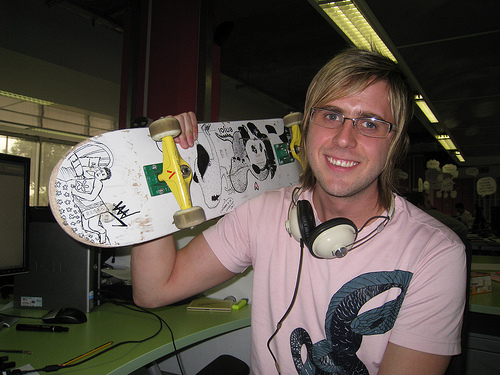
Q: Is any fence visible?
A: No, there are no fences.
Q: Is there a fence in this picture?
A: No, there are no fences.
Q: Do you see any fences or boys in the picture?
A: No, there are no fences or boys.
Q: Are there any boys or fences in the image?
A: No, there are no fences or boys.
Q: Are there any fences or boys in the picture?
A: No, there are no fences or boys.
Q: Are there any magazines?
A: No, there are no magazines.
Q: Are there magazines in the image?
A: No, there are no magazines.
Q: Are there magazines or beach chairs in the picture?
A: No, there are no magazines or beach chairs.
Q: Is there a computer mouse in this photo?
A: Yes, there is a computer mouse.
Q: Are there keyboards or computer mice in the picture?
A: Yes, there is a computer mouse.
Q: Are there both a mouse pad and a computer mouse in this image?
A: No, there is a computer mouse but no mouse pads.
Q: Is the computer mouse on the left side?
A: Yes, the computer mouse is on the left of the image.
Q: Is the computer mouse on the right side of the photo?
A: No, the computer mouse is on the left of the image.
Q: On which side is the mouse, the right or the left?
A: The mouse is on the left of the image.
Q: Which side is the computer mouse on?
A: The computer mouse is on the left of the image.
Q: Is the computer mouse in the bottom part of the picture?
A: Yes, the computer mouse is in the bottom of the image.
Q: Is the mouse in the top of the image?
A: No, the mouse is in the bottom of the image.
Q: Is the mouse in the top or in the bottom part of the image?
A: The mouse is in the bottom of the image.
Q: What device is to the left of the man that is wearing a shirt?
A: The device is a computer mouse.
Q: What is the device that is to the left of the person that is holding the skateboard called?
A: The device is a computer mouse.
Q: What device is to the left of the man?
A: The device is a computer mouse.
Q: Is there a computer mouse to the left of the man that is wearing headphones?
A: Yes, there is a computer mouse to the left of the man.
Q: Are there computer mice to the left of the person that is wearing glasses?
A: Yes, there is a computer mouse to the left of the man.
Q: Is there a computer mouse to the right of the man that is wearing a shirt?
A: No, the computer mouse is to the left of the man.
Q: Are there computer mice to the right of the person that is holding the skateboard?
A: No, the computer mouse is to the left of the man.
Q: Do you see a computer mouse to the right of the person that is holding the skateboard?
A: No, the computer mouse is to the left of the man.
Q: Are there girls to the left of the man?
A: No, there is a computer mouse to the left of the man.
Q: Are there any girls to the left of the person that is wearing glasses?
A: No, there is a computer mouse to the left of the man.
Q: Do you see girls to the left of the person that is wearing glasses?
A: No, there is a computer mouse to the left of the man.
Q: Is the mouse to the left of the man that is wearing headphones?
A: Yes, the mouse is to the left of the man.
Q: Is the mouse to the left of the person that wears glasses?
A: Yes, the mouse is to the left of the man.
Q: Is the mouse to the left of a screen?
A: No, the mouse is to the left of the man.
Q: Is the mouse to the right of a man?
A: No, the mouse is to the left of a man.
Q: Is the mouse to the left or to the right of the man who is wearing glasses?
A: The mouse is to the left of the man.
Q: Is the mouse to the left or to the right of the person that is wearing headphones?
A: The mouse is to the left of the man.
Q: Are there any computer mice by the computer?
A: Yes, there is a computer mouse by the computer.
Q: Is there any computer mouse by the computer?
A: Yes, there is a computer mouse by the computer.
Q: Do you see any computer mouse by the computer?
A: Yes, there is a computer mouse by the computer.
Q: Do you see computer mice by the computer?
A: Yes, there is a computer mouse by the computer.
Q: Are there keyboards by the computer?
A: No, there is a computer mouse by the computer.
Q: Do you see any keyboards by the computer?
A: No, there is a computer mouse by the computer.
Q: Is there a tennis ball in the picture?
A: No, there are no tennis balls.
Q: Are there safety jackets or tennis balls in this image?
A: No, there are no tennis balls or safety jackets.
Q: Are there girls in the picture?
A: No, there are no girls.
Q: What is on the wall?
A: The drawings are on the wall.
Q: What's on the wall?
A: The drawings are on the wall.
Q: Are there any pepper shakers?
A: No, there are no pepper shakers.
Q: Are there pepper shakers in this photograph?
A: No, there are no pepper shakers.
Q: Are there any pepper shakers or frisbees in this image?
A: No, there are no pepper shakers or frisbees.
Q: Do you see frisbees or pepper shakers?
A: No, there are no pepper shakers or frisbees.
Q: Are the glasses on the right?
A: Yes, the glasses are on the right of the image.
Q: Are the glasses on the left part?
A: No, the glasses are on the right of the image.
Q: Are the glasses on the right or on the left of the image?
A: The glasses are on the right of the image.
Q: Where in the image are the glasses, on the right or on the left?
A: The glasses are on the right of the image.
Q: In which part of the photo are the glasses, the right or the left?
A: The glasses are on the right of the image.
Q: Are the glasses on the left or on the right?
A: The glasses are on the right of the image.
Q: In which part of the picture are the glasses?
A: The glasses are on the right of the image.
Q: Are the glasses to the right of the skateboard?
A: Yes, the glasses are to the right of the skateboard.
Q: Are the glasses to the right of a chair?
A: No, the glasses are to the right of the skateboard.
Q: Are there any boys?
A: No, there are no boys.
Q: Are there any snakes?
A: Yes, there is a snake.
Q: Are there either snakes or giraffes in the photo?
A: Yes, there is a snake.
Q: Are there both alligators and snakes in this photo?
A: No, there is a snake but no alligators.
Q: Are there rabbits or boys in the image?
A: No, there are no boys or rabbits.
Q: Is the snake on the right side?
A: Yes, the snake is on the right of the image.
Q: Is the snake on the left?
A: No, the snake is on the right of the image.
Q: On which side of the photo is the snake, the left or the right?
A: The snake is on the right of the image.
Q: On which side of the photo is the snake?
A: The snake is on the right of the image.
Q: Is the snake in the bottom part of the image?
A: Yes, the snake is in the bottom of the image.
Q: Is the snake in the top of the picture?
A: No, the snake is in the bottom of the image.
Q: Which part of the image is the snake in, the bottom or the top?
A: The snake is in the bottom of the image.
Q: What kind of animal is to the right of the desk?
A: The animal is a snake.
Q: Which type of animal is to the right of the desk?
A: The animal is a snake.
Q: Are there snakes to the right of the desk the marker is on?
A: Yes, there is a snake to the right of the desk.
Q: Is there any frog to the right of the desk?
A: No, there is a snake to the right of the desk.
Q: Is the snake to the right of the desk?
A: Yes, the snake is to the right of the desk.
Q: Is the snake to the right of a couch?
A: No, the snake is to the right of the desk.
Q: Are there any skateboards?
A: Yes, there is a skateboard.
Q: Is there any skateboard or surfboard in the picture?
A: Yes, there is a skateboard.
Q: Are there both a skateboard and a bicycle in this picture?
A: No, there is a skateboard but no bicycles.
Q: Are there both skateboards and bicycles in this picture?
A: No, there is a skateboard but no bicycles.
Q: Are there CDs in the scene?
A: No, there are no cds.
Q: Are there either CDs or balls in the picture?
A: No, there are no CDs or balls.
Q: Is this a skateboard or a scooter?
A: This is a skateboard.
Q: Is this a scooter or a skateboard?
A: This is a skateboard.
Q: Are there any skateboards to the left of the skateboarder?
A: Yes, there is a skateboard to the left of the skateboarder.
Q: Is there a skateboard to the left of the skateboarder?
A: Yes, there is a skateboard to the left of the skateboarder.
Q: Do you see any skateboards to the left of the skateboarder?
A: Yes, there is a skateboard to the left of the skateboarder.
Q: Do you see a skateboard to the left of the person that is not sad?
A: Yes, there is a skateboard to the left of the skateboarder.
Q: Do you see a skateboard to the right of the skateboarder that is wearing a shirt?
A: No, the skateboard is to the left of the skateboarder.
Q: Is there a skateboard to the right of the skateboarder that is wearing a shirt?
A: No, the skateboard is to the left of the skateboarder.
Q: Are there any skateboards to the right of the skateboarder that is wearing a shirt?
A: No, the skateboard is to the left of the skateboarder.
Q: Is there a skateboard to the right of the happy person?
A: No, the skateboard is to the left of the skateboarder.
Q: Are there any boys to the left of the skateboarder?
A: No, there is a skateboard to the left of the skateboarder.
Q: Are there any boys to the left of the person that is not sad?
A: No, there is a skateboard to the left of the skateboarder.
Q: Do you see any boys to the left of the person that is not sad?
A: No, there is a skateboard to the left of the skateboarder.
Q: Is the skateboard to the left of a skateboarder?
A: Yes, the skateboard is to the left of a skateboarder.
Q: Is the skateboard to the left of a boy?
A: No, the skateboard is to the left of a skateboarder.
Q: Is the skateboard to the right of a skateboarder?
A: No, the skateboard is to the left of a skateboarder.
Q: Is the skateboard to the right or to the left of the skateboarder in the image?
A: The skateboard is to the left of the skateboarder.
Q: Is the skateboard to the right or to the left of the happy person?
A: The skateboard is to the left of the skateboarder.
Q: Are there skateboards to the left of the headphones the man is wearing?
A: Yes, there is a skateboard to the left of the headphones.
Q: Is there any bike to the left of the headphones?
A: No, there is a skateboard to the left of the headphones.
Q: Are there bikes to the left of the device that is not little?
A: No, there is a skateboard to the left of the headphones.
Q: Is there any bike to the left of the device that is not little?
A: No, there is a skateboard to the left of the headphones.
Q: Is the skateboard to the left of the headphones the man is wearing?
A: Yes, the skateboard is to the left of the headphones.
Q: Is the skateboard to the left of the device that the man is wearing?
A: Yes, the skateboard is to the left of the headphones.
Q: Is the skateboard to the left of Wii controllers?
A: No, the skateboard is to the left of the headphones.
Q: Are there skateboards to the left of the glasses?
A: Yes, there is a skateboard to the left of the glasses.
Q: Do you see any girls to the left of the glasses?
A: No, there is a skateboard to the left of the glasses.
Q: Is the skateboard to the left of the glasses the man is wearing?
A: Yes, the skateboard is to the left of the glasses.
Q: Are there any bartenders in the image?
A: No, there are no bartenders.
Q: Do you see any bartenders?
A: No, there are no bartenders.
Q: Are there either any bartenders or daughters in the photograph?
A: No, there are no bartenders or daughters.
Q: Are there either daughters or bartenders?
A: No, there are no bartenders or daughters.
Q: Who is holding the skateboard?
A: The man is holding the skateboard.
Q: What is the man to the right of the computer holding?
A: The man is holding the skateboard.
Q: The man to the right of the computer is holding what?
A: The man is holding the skateboard.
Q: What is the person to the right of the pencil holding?
A: The man is holding the skateboard.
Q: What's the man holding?
A: The man is holding the skateboard.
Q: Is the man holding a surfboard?
A: No, the man is holding the skateboard.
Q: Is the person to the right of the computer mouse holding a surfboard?
A: No, the man is holding the skateboard.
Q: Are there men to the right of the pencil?
A: Yes, there is a man to the right of the pencil.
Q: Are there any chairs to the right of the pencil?
A: No, there is a man to the right of the pencil.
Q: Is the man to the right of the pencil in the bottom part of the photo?
A: Yes, the man is to the right of the pencil.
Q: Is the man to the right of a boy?
A: No, the man is to the right of the pencil.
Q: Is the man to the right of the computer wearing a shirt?
A: Yes, the man is wearing a shirt.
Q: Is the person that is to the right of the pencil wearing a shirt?
A: Yes, the man is wearing a shirt.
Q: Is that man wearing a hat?
A: No, the man is wearing a shirt.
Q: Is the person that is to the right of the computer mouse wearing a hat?
A: No, the man is wearing a shirt.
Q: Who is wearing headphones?
A: The man is wearing headphones.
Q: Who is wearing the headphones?
A: The man is wearing headphones.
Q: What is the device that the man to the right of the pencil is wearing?
A: The device is headphones.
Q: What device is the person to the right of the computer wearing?
A: The man is wearing headphones.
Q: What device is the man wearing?
A: The man is wearing headphones.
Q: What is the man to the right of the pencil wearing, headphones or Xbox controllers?
A: The man is wearing headphones.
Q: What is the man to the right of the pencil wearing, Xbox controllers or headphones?
A: The man is wearing headphones.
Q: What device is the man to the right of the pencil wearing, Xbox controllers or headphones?
A: The man is wearing headphones.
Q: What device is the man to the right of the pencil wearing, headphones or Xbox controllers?
A: The man is wearing headphones.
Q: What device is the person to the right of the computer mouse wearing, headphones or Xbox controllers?
A: The man is wearing headphones.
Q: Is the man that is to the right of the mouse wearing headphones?
A: Yes, the man is wearing headphones.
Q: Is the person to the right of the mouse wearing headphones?
A: Yes, the man is wearing headphones.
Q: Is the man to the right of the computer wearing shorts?
A: No, the man is wearing headphones.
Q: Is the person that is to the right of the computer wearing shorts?
A: No, the man is wearing headphones.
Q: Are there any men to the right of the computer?
A: Yes, there is a man to the right of the computer.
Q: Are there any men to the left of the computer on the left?
A: No, the man is to the right of the computer.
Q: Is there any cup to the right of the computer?
A: No, there is a man to the right of the computer.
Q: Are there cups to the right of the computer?
A: No, there is a man to the right of the computer.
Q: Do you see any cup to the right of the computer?
A: No, there is a man to the right of the computer.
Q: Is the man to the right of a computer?
A: Yes, the man is to the right of a computer.